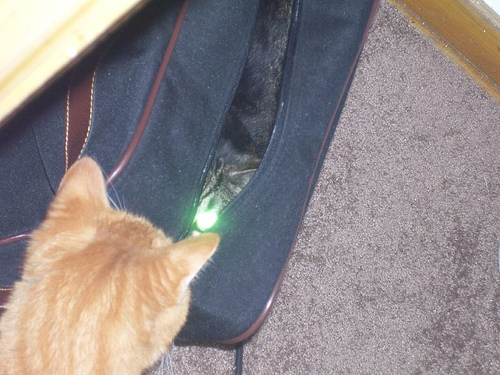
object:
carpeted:
[385, 110, 462, 250]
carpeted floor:
[370, 87, 464, 240]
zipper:
[178, 0, 306, 242]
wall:
[383, 0, 497, 87]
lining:
[0, 0, 188, 247]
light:
[191, 195, 224, 237]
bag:
[0, 0, 383, 346]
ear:
[155, 227, 228, 293]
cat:
[192, 0, 303, 204]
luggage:
[0, 0, 388, 345]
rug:
[152, 0, 500, 375]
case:
[0, 0, 380, 373]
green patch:
[424, 78, 439, 95]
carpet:
[360, 311, 497, 370]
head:
[0, 155, 221, 369]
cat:
[0, 156, 221, 375]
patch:
[430, 210, 498, 270]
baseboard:
[395, 0, 499, 91]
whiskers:
[104, 162, 124, 207]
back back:
[0, 0, 383, 343]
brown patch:
[350, 95, 379, 119]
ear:
[46, 155, 109, 211]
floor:
[341, 104, 449, 207]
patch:
[290, 283, 340, 329]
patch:
[398, 123, 438, 155]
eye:
[189, 200, 216, 233]